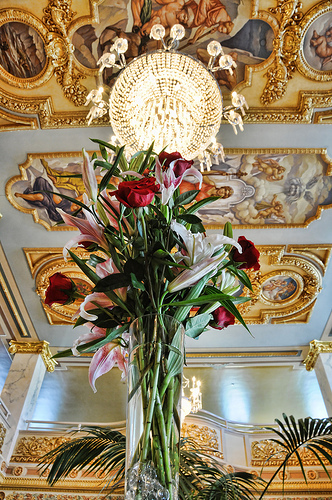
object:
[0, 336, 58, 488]
pillar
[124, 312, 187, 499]
vase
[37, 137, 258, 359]
bouquet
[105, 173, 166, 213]
rose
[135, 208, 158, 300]
stem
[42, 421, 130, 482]
palm frond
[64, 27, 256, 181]
chandelier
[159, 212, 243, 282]
flower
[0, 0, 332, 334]
panels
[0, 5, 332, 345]
ceiling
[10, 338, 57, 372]
molding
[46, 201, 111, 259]
flower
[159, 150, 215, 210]
day lily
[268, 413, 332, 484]
plant fronds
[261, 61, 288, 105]
decorations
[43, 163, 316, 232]
mural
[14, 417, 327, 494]
balcony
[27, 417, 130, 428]
railing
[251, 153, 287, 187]
angel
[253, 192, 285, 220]
cherubs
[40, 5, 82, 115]
cornucopias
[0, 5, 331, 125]
relief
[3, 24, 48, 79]
painting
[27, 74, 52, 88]
frame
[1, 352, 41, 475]
column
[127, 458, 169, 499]
stones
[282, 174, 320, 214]
god